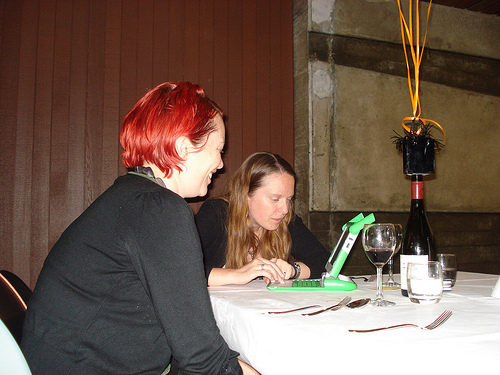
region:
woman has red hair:
[87, 72, 245, 220]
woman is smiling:
[107, 66, 240, 212]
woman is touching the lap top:
[224, 147, 375, 299]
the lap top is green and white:
[257, 194, 364, 301]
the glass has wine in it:
[353, 207, 400, 307]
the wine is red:
[355, 209, 402, 284]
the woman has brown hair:
[217, 135, 304, 270]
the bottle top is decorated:
[380, 9, 442, 269]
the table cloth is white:
[245, 265, 474, 365]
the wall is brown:
[8, 38, 293, 147]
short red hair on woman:
[118, 80, 225, 172]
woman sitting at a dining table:
[16, 80, 261, 373]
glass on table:
[363, 220, 395, 306]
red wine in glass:
[368, 248, 393, 262]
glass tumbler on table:
[407, 260, 445, 304]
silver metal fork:
[348, 308, 453, 333]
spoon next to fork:
[303, 297, 373, 314]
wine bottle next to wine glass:
[399, 173, 436, 298]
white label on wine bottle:
[398, 253, 428, 288]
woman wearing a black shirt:
[18, 171, 245, 372]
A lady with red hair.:
[16, 78, 261, 373]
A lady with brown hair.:
[195, 150, 344, 286]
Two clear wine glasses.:
[362, 221, 402, 308]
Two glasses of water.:
[406, 255, 459, 305]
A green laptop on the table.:
[266, 210, 375, 292]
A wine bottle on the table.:
[400, 173, 437, 297]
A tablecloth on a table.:
[206, 270, 499, 373]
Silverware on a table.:
[268, 295, 452, 333]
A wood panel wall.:
[1, 2, 296, 295]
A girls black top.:
[21, 165, 242, 374]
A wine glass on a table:
[336, 203, 422, 333]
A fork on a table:
[345, 308, 494, 330]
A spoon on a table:
[274, 288, 390, 337]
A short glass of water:
[404, 239, 441, 307]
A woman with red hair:
[11, 36, 296, 372]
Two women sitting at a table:
[1, 21, 489, 373]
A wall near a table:
[12, 13, 128, 225]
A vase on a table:
[356, 8, 483, 301]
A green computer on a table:
[258, 213, 387, 316]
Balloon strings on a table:
[348, 6, 457, 147]